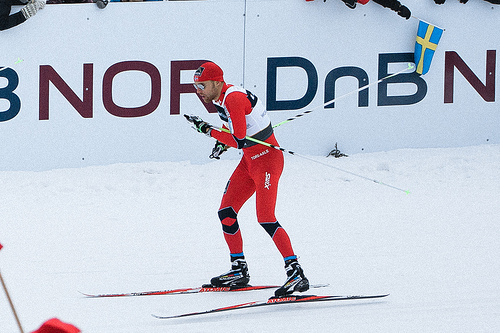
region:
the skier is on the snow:
[75, 56, 415, 321]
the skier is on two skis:
[78, 282, 386, 317]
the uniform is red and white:
[76, 62, 386, 319]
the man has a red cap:
[191, 64, 225, 84]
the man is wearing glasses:
[191, 80, 204, 94]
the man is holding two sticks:
[190, 65, 415, 193]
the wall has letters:
[0, 1, 499, 171]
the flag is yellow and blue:
[411, 19, 444, 72]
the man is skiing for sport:
[78, 65, 410, 320]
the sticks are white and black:
[195, 63, 403, 193]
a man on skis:
[69, 28, 373, 326]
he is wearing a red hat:
[157, 51, 249, 133]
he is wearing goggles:
[171, 53, 246, 120]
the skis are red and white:
[51, 244, 401, 327]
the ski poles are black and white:
[174, 58, 420, 211]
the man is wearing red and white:
[159, 65, 393, 330]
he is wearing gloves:
[171, 100, 241, 175]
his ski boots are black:
[200, 233, 309, 328]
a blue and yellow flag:
[393, 12, 460, 98]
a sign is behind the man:
[6, 20, 486, 211]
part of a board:
[422, 105, 444, 119]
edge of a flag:
[405, 12, 419, 52]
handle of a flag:
[424, 21, 438, 32]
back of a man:
[250, 88, 257, 110]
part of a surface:
[421, 232, 453, 250]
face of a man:
[201, 80, 214, 98]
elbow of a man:
[236, 130, 248, 151]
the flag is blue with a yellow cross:
[411, 13, 462, 83]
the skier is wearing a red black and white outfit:
[169, 57, 379, 329]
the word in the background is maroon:
[28, 57, 211, 121]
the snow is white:
[398, 224, 498, 290]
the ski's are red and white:
[78, 275, 420, 327]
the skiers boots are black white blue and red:
[201, 248, 351, 307]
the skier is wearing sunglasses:
[176, 60, 242, 109]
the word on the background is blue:
[255, 47, 433, 122]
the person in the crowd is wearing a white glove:
[13, 0, 69, 27]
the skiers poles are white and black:
[174, 42, 483, 244]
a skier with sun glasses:
[191, 67, 209, 99]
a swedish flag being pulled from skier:
[385, 20, 456, 77]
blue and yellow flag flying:
[411, 18, 446, 78]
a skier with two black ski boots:
[193, 249, 318, 296]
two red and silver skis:
[76, 262, 396, 332]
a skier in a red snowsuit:
[84, 53, 411, 331]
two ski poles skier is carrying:
[183, 63, 433, 214]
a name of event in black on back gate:
[0, 45, 498, 155]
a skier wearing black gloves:
[169, 107, 225, 157]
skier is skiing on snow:
[5, 60, 499, 329]